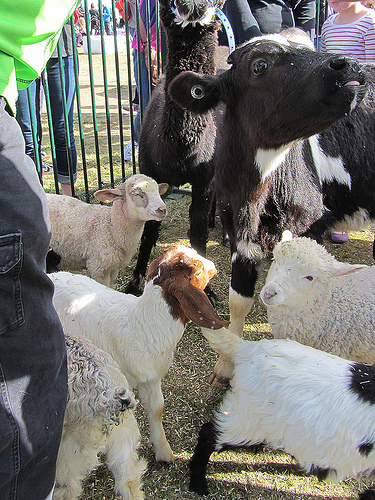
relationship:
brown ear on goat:
[165, 275, 232, 331] [44, 242, 220, 464]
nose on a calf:
[319, 54, 362, 71] [178, 44, 373, 237]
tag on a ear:
[191, 82, 207, 103] [166, 71, 228, 116]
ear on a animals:
[166, 71, 228, 116] [166, 30, 375, 382]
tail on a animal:
[198, 324, 245, 359] [186, 322, 375, 498]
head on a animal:
[258, 227, 360, 308] [258, 227, 373, 364]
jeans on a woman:
[11, 54, 84, 194] [13, 4, 89, 196]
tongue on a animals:
[341, 79, 358, 85] [166, 30, 375, 382]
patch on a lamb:
[127, 186, 148, 207] [40, 171, 171, 288]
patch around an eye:
[127, 186, 148, 207] [132, 191, 144, 199]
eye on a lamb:
[132, 191, 144, 199] [40, 171, 171, 288]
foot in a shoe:
[195, 353, 257, 396] [330, 232, 353, 242]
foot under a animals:
[195, 353, 257, 396] [166, 30, 375, 382]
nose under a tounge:
[324, 55, 363, 75] [344, 75, 362, 88]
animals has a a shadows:
[54, 9, 369, 380] [64, 90, 128, 175]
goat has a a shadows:
[44, 242, 232, 464] [64, 90, 128, 175]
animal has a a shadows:
[260, 227, 373, 364] [64, 90, 128, 175]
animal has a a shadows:
[186, 322, 374, 497] [64, 90, 128, 175]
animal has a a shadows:
[41, 172, 169, 287] [64, 90, 128, 175]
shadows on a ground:
[64, 90, 128, 175] [18, 54, 373, 498]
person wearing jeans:
[0, 1, 71, 498] [1, 94, 100, 497]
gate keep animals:
[25, 2, 163, 207] [122, 0, 235, 300]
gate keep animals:
[25, 2, 163, 207] [164, 32, 374, 380]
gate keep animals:
[25, 2, 163, 207] [258, 227, 374, 366]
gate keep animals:
[25, 2, 163, 207] [187, 317, 374, 497]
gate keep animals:
[25, 2, 163, 207] [39, 173, 169, 293]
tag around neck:
[208, 0, 256, 78] [161, 8, 226, 44]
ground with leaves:
[167, 346, 207, 407] [167, 410, 184, 430]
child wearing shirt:
[321, 2, 371, 62] [318, 7, 373, 62]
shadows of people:
[94, 87, 138, 101] [115, 0, 159, 166]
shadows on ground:
[94, 87, 138, 101] [18, 54, 373, 498]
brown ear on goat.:
[167, 275, 232, 331] [42, 243, 229, 446]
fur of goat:
[52, 302, 188, 458] [52, 332, 151, 500]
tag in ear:
[190, 83, 206, 100] [167, 71, 231, 113]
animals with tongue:
[166, 30, 375, 382] [343, 77, 359, 87]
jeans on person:
[15, 46, 79, 187] [0, 1, 71, 498]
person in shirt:
[0, 1, 71, 498] [0, 1, 88, 119]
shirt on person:
[4, 2, 89, 102] [0, 0, 83, 499]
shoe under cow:
[330, 229, 350, 242] [169, 27, 374, 330]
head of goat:
[144, 242, 231, 329] [44, 242, 232, 464]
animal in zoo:
[258, 227, 373, 364] [0, 0, 373, 499]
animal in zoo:
[186, 322, 375, 498] [0, 0, 373, 499]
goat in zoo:
[44, 242, 232, 464] [0, 0, 373, 499]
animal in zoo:
[44, 174, 170, 292] [0, 0, 373, 499]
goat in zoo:
[61, 324, 141, 499] [0, 0, 373, 499]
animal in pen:
[44, 174, 170, 292] [36, 21, 226, 186]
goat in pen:
[44, 242, 220, 464] [36, 21, 226, 186]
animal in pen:
[186, 322, 375, 498] [36, 21, 226, 186]